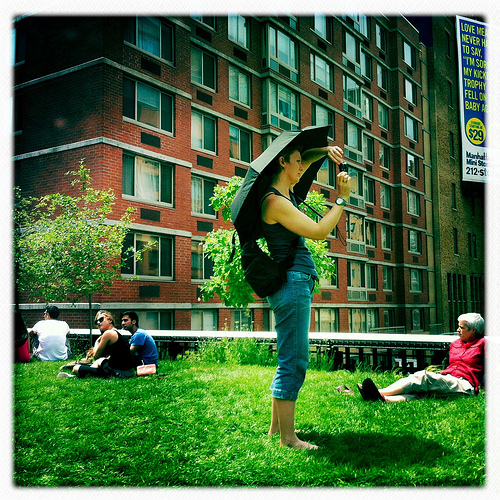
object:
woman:
[253, 143, 352, 454]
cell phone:
[339, 161, 351, 176]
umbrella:
[225, 123, 333, 237]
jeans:
[266, 269, 307, 403]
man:
[357, 309, 483, 409]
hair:
[454, 310, 485, 335]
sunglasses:
[91, 317, 108, 325]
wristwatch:
[333, 196, 347, 210]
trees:
[17, 156, 158, 350]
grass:
[9, 336, 488, 483]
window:
[120, 149, 180, 209]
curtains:
[134, 155, 163, 201]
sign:
[453, 14, 485, 187]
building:
[422, 13, 490, 336]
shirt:
[440, 336, 485, 395]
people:
[55, 310, 129, 382]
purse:
[237, 237, 289, 300]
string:
[227, 227, 240, 263]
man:
[28, 304, 73, 360]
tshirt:
[258, 189, 319, 281]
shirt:
[125, 328, 159, 368]